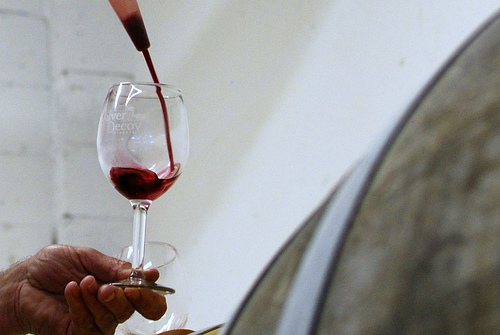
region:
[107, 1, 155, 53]
the spout is attached to a wine bottle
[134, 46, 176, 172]
red wine is being poured into the glass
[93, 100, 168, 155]
writing is on the side of the glass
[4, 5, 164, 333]
part of the wall is made with cement bricks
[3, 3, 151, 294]
the bricks are white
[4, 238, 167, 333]
the glass is being held in a persons hand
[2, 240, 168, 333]
the hand belongs to a man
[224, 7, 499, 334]
the person is beside the side of a car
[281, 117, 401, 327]
the frame between front and back door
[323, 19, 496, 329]
the window is tinted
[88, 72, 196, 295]
A person holding a wine glass.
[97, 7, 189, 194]
Person pouring wine in glass.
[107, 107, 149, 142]
Wine glass has writings.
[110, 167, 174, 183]
The wine is red.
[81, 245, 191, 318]
Fingers on bottom of glass.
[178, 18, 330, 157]
Wall is white.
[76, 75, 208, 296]
The glass is tall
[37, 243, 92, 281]
Wrinkles on hand.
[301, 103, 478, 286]
Barrel in front of person.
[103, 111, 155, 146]
The writing is white.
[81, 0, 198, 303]
red wine being poured into a glass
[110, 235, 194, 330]
an empty wine glass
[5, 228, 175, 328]
hand holding the bottom of a wine glass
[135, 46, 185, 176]
stream of red wine being poured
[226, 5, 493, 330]
a wooden wine barrel in the background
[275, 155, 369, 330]
metal ban on a wooden wine barrel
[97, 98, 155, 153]
winery's logo on a wine glass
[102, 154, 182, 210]
red wine in a wine glass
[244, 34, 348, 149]
white wall of a wine cellar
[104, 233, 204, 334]
empty wine glass waiting to be filled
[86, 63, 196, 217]
Wine poured into glass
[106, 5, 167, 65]
Tip of wine bottle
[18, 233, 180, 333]
Left hand of man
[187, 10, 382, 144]
White wall in background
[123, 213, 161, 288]
Stem of wine glass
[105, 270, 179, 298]
Circular bottom of glass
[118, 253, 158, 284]
Thumb of man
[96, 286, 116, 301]
Middle finger has fingernail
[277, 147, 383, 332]
Metal clasp in background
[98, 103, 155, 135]
Label on wine glass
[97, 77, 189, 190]
this is a glass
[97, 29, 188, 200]
wine is being poured in the glass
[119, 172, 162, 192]
the wine is red in color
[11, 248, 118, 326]
this is a hand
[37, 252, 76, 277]
the hand is white in color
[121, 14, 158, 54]
this is the mouth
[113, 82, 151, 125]
the glass is clear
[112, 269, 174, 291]
this is the base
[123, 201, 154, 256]
the stem is thin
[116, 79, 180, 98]
the mouth is wide